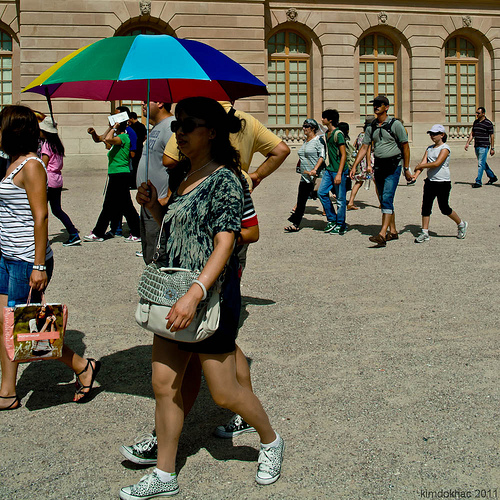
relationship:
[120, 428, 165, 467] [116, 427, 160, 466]
shoe on foot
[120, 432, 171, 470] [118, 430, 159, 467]
shoe on foot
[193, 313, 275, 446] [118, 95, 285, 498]
leg of a girl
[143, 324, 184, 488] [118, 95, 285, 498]
leg of a girl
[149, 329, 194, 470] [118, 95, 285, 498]
leg of a girl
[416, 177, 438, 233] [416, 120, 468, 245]
leg of a person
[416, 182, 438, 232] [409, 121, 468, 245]
leg of a girl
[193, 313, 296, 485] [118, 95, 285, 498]
leg of a girl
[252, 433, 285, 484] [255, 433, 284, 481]
shoe covering foot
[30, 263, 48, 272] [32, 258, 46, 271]
watch worn around wrist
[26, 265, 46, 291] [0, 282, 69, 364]
hand holding bag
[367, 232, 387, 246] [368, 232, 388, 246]
shoe covering foot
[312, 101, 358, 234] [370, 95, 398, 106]
man wearing hat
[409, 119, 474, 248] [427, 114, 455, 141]
girl wearing hat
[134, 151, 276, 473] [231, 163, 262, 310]
girl wearing shirts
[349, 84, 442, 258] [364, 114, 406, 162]
man wearing shirt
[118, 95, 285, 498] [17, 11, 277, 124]
girl holding umbrella